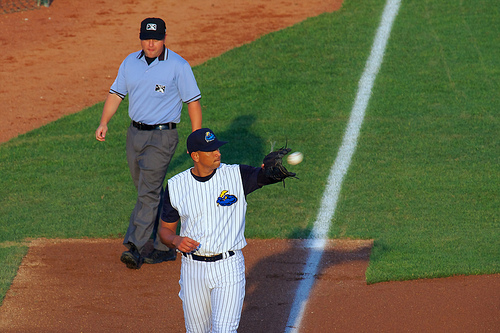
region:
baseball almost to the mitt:
[289, 148, 308, 173]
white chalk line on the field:
[331, 64, 382, 186]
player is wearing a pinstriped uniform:
[166, 180, 258, 304]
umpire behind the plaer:
[82, 6, 189, 231]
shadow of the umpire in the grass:
[224, 101, 258, 153]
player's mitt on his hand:
[256, 142, 306, 182]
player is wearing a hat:
[181, 120, 219, 147]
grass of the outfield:
[380, 83, 470, 250]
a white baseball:
[288, 144, 302, 169]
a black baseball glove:
[259, 143, 296, 181]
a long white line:
[276, 1, 404, 331]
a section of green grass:
[320, 0, 498, 292]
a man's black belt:
[127, 119, 177, 133]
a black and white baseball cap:
[137, 15, 167, 41]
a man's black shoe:
[112, 247, 144, 272]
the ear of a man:
[188, 151, 200, 163]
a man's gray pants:
[121, 125, 176, 257]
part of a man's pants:
[175, 255, 247, 329]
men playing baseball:
[65, 76, 328, 323]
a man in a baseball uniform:
[109, 114, 284, 319]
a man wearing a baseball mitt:
[162, 125, 354, 330]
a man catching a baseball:
[157, 123, 360, 326]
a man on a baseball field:
[158, 93, 333, 318]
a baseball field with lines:
[224, 19, 499, 276]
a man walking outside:
[92, 39, 228, 226]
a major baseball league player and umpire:
[69, 4, 318, 329]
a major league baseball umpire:
[85, 14, 205, 269]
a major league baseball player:
[155, 108, 312, 332]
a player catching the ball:
[124, 125, 322, 330]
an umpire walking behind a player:
[65, 12, 216, 287]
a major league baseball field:
[268, 1, 496, 330]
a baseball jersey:
[151, 163, 271, 258]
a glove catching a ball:
[256, 141, 307, 188]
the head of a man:
[171, 122, 228, 177]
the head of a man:
[131, 7, 178, 71]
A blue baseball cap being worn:
[185, 127, 230, 151]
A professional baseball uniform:
[154, 166, 246, 331]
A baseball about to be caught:
[287, 152, 302, 165]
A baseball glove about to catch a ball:
[264, 148, 294, 180]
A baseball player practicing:
[156, 128, 302, 331]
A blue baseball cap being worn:
[137, 16, 164, 38]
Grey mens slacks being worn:
[122, 118, 174, 261]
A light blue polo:
[109, 50, 200, 124]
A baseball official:
[93, 17, 202, 265]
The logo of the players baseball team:
[217, 191, 237, 207]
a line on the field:
[272, 34, 424, 301]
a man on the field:
[94, 21, 294, 281]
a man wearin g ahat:
[181, 111, 261, 211]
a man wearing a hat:
[122, 4, 193, 106]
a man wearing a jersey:
[104, 124, 250, 274]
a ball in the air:
[270, 111, 332, 189]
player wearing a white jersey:
[143, 148, 272, 249]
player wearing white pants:
[159, 250, 251, 331]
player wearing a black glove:
[258, 148, 299, 183]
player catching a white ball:
[283, 145, 306, 163]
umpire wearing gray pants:
[113, 124, 168, 254]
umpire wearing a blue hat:
[126, 16, 161, 36]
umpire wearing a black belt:
[127, 120, 169, 135]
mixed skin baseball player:
[176, 130, 263, 330]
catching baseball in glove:
[261, 149, 316, 186]